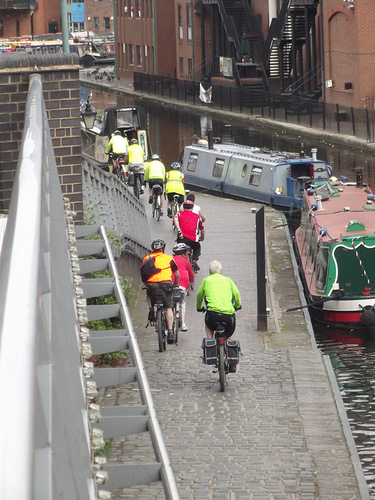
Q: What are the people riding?
A: Bicycles.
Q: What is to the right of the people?
A: Water.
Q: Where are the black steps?
A: Near building.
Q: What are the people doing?
A: Biking.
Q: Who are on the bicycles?
A: Bikers.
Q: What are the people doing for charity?
A: Riding bikes.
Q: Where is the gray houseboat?
A: In canal.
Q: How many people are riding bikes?
A: Nine.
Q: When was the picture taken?
A: Daytime.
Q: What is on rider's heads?
A: Helmets.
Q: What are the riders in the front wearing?
A: Yellow shirts.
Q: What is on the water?
A: Two boats.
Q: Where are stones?
A: On the ground.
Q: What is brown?
A: Buildings.